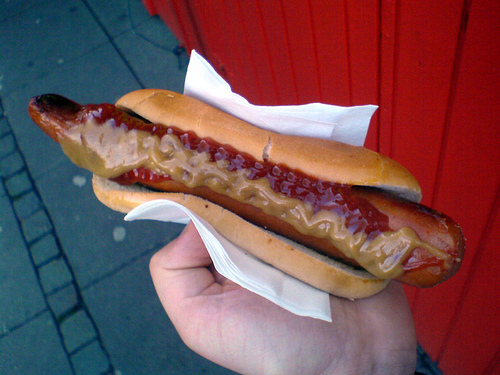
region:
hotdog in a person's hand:
[25, 45, 465, 373]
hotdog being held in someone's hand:
[18, 46, 468, 371]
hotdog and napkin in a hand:
[23, 45, 466, 372]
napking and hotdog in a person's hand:
[21, 42, 473, 374]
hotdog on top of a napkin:
[21, 45, 472, 325]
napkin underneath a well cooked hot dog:
[23, 45, 465, 325]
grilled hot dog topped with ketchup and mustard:
[20, 64, 482, 304]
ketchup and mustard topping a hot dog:
[19, 72, 471, 303]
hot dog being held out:
[24, 47, 467, 372]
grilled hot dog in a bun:
[19, 80, 471, 302]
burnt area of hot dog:
[27, 83, 87, 124]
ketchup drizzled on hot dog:
[87, 91, 388, 233]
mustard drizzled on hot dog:
[42, 125, 430, 309]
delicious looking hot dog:
[11, 72, 453, 317]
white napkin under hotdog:
[125, 36, 393, 341]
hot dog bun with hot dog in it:
[132, 85, 410, 203]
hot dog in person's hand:
[30, 75, 458, 316]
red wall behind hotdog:
[155, 0, 497, 352]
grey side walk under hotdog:
[1, 6, 209, 367]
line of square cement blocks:
[2, 123, 114, 373]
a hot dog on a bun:
[20, 80, 469, 301]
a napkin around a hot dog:
[173, 46, 373, 156]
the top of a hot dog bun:
[117, 87, 427, 197]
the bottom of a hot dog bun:
[245, 230, 387, 305]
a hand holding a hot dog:
[136, 194, 471, 358]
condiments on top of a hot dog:
[67, 103, 245, 184]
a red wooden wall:
[316, 23, 489, 108]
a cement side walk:
[6, 190, 98, 367]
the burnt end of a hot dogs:
[24, 89, 74, 134]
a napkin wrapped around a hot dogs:
[210, 240, 337, 329]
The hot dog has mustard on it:
[13, 55, 486, 310]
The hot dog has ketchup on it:
[36, 67, 490, 314]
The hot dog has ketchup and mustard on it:
[23, 52, 483, 344]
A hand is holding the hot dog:
[23, 51, 473, 360]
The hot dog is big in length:
[37, 63, 463, 311]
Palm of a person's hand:
[142, 242, 425, 372]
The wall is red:
[247, 7, 445, 104]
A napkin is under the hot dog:
[133, 197, 343, 349]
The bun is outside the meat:
[36, 85, 487, 310]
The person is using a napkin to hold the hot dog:
[37, 38, 474, 311]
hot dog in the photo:
[23, 58, 443, 288]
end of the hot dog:
[361, 160, 482, 295]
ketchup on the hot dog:
[109, 112, 335, 232]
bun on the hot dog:
[159, 80, 377, 202]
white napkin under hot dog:
[173, 207, 265, 307]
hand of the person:
[148, 240, 397, 371]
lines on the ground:
[9, 247, 116, 359]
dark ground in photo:
[29, 240, 121, 355]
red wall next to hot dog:
[292, 9, 464, 79]